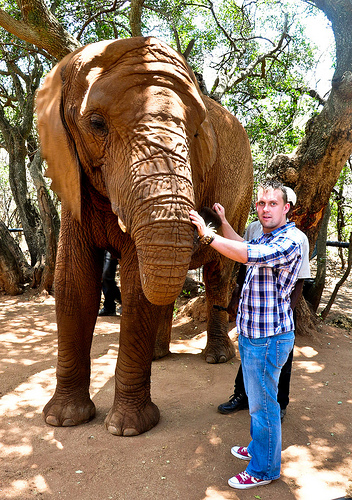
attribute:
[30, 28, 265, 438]
elephant — big, huge, wrinkled, old, standing, giagantic, sad, thick, rusty, dirty, large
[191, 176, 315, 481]
man — white, young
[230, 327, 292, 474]
pants — blue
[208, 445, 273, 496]
shoes — red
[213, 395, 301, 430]
shoes — black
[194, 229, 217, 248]
bracelet — black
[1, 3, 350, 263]
trees — green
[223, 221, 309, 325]
shirt — plaid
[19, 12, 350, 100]
sky — white, clear